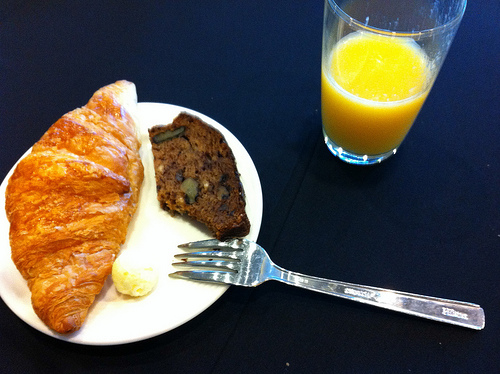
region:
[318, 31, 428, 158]
orange juice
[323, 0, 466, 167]
a tall clear glass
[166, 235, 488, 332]
a silver fork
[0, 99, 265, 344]
a circle shaped white plate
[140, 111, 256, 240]
a piece of meat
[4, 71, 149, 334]
a croissant piece of bread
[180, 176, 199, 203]
a green bell pepper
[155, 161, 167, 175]
a small piece of onion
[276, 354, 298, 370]
a small bread crumb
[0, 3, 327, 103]
part of a blue tablecloth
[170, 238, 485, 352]
an upside down silver fork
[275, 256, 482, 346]
the handle of an upside down silver fork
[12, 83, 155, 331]
a brown croissant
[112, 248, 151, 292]
a ball of butter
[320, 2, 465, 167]
a clear glass cup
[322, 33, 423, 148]
orange juice in a clear glass cup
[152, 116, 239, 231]
a piece of meatloaf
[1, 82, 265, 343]
a small white plate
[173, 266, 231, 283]
the prong of a fork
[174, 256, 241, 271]
the prong of a fork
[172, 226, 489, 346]
Fork on a plate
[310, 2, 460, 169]
Glass of orange juice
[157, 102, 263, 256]
slice of toast on plate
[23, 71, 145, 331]
A large crossant with dab of butter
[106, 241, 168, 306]
round ball of butter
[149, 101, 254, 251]
Looks like nuts in the bread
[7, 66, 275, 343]
Food on a white plate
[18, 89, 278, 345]
Round white plate on table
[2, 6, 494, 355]
Table has blue table cloth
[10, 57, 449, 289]
Plate next to glass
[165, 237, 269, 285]
Fork tines on a white plate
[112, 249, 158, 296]
Pat of butter on a plate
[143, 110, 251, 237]
Fruit cake on a plate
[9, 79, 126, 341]
Croissant on a plate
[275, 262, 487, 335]
Fork handle on a table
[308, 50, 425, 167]
Orange juice in a glass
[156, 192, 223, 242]
Bite taken out of a fruit cake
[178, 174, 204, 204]
Fruit and nuts baked in a slice of cake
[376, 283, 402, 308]
Light reflecting off of a fork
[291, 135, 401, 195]
Shadow of a glass on a table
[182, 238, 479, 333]
silver fork on table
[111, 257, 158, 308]
mound of butter on plate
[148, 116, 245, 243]
piece of meat on plate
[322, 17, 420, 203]
clear glass with orange juice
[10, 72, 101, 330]
large flaky croissant on plate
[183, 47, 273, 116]
black table top surface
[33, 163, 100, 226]
crusty brown pastry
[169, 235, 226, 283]
four tines on fork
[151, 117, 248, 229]
brown meat on plate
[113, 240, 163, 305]
yellow piece of butter